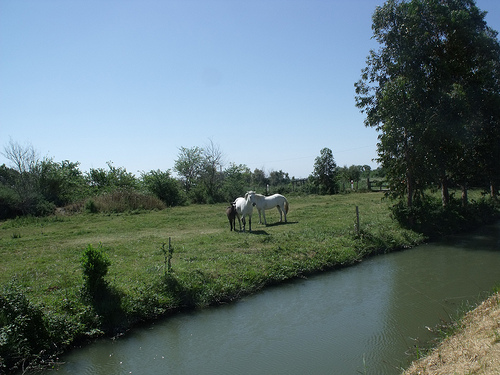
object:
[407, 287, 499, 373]
grass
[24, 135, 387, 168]
cloud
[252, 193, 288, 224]
horse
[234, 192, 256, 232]
horse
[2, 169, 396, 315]
grass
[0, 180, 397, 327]
field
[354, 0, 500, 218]
tree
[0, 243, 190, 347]
plant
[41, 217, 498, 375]
stream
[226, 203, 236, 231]
baby horse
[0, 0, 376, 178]
skies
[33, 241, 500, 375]
water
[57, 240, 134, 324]
bush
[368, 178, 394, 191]
fence gate